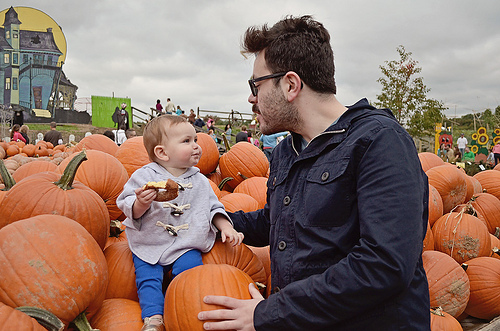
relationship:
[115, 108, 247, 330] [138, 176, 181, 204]
infant holding donut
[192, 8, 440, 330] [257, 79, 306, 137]
man has whiskers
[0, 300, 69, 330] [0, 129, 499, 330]
pumpkin in pile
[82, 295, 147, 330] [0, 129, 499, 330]
pumpkin in pile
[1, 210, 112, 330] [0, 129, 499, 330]
pumpkin in pile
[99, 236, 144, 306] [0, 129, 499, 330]
pumpkin in pile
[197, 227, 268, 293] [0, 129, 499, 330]
pumpkin in pile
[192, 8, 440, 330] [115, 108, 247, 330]
man beside infant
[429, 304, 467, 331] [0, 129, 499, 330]
pumpkin in pile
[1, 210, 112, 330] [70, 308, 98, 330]
pumpkin has stem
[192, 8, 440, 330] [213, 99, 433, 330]
man wearing jacket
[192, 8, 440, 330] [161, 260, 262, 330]
man touching pumpkin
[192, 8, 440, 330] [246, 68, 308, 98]
man wearing glasses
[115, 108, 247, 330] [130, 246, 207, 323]
infant wearing pants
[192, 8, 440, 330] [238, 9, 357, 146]
man has head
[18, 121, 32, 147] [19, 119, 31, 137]
woman has head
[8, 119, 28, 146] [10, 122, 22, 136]
woman has head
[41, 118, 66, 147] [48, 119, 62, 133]
man has head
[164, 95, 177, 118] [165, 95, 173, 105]
man has head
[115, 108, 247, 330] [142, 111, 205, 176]
infant has head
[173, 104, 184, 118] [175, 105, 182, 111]
woman has head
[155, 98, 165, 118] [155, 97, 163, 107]
woman has head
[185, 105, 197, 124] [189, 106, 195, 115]
woman has head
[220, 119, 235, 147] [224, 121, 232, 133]
woman has head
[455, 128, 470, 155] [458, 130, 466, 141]
man has head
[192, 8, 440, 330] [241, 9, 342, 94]
man has hair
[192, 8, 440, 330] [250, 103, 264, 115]
man has moustache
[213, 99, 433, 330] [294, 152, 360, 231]
jacket has pocket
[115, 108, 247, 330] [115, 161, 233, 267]
infant wearing jacket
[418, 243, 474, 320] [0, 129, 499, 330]
pumpkin on pile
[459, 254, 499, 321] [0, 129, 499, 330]
pumpkin on pile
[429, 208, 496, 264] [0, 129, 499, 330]
pumpkin on pile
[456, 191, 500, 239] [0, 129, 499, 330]
pumpkin on pile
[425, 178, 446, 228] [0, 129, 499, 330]
pumpkin on pile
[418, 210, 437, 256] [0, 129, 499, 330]
pumpkin on pile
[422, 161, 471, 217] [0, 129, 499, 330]
pumpkin on pile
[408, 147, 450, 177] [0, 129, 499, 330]
pumpkin on pile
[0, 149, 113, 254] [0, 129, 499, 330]
pumpkin on pile